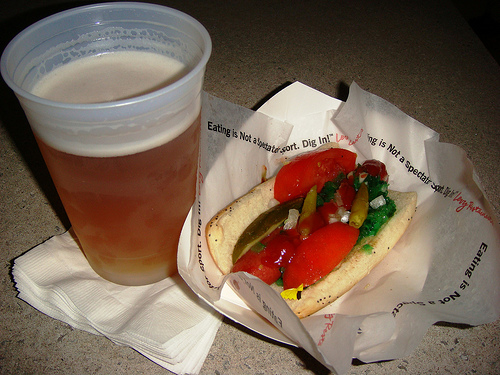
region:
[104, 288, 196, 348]
one hot dog is seen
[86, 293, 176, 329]
white color tissue paper.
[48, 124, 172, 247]
cool drinks in brown in color.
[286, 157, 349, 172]
tomato is red in color.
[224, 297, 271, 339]
box is white in color.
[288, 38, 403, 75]
table is grey in color.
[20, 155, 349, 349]
things are kept in the floor.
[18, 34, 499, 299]
night time picture.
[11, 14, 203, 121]
tumbler is white in color.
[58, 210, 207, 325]
tissue paper is under the tumbler.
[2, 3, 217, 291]
A PLASTIC CUP OF BEER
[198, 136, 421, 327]
A HOT DOG IN A BUN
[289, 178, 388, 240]
TWO HOT PEPPERS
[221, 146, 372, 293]
TWO TOMATOES AND A PICKLE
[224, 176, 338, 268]
A PICKLE ON THE SIDE OF THE HOT DOG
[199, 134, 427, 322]
A POPPY SEED BUN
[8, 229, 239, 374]
A STACK OF NAPKINS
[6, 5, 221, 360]
A PLASTIC CUP ON SOME NAPKINS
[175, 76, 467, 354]
A HOT DOG ON WAX PAPER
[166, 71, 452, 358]
A CARDBOARD CONTAINER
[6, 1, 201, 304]
plastic cup of beer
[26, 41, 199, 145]
white foam on top of beer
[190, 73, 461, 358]
paper basket with hot dog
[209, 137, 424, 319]
hot dog in bun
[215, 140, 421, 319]
hot dog with pickle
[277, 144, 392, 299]
peppers and ketchup on hot dog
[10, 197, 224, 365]
pile of white napkins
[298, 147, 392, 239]
green relish on hot dog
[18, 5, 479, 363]
beer with a hot dog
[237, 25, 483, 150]
mottled brown countertop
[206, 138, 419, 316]
A hotdog in a bun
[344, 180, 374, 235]
A pepper on the hotdog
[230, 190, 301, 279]
A pickle next to the hotdog with ketchup on the hotdog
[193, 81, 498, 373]
White paper with wording underneath the hotdog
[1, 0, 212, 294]
A beverage in a plastic cup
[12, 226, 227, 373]
White Napkins underneath the cup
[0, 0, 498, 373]
Lunch sitting on a granite counter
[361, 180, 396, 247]
Green condiment with a piece of onion on the hotdog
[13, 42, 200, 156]
Foam on the top of the drink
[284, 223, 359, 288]
A red pepper inside the hotdog bun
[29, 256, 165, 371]
Stack of white napkins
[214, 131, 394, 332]
Sandwich with tomatoes and peppers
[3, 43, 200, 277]
Plastic cup with a foaming beverage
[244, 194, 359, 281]
Pickle and peppers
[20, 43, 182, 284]
Hazelnut colored beverage with foam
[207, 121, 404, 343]
Sandwich with red and green toppings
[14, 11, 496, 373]
Sandwich and drink combo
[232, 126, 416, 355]
Spicy tomato sandwich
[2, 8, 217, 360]
Cup sitting on stack of napkins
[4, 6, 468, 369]
Napkins, drink and sandwich